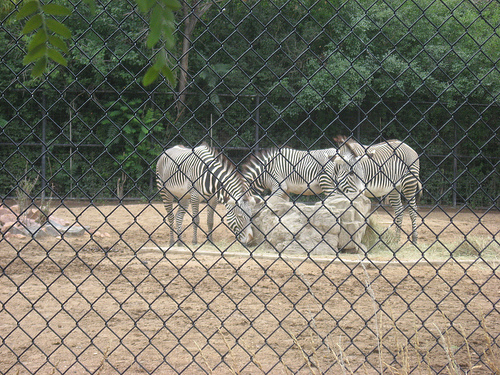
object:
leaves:
[45, 17, 72, 40]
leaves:
[161, 65, 175, 88]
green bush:
[0, 0, 499, 206]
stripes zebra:
[241, 143, 340, 203]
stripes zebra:
[328, 135, 423, 246]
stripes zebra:
[155, 140, 262, 248]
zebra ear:
[356, 150, 375, 163]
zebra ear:
[328, 153, 346, 164]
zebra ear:
[224, 196, 240, 206]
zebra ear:
[250, 195, 263, 208]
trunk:
[452, 123, 457, 207]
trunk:
[357, 103, 361, 141]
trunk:
[379, 117, 382, 142]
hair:
[201, 141, 249, 203]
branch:
[177, 0, 215, 119]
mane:
[333, 135, 359, 165]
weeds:
[9, 157, 55, 227]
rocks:
[0, 204, 90, 239]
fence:
[0, 1, 499, 374]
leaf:
[15, 5, 40, 20]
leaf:
[40, 3, 73, 16]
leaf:
[142, 67, 160, 86]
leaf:
[162, 20, 176, 49]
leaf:
[46, 48, 68, 66]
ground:
[1, 203, 500, 374]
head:
[222, 196, 261, 245]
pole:
[40, 91, 46, 197]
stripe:
[285, 147, 286, 174]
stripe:
[290, 149, 295, 181]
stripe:
[296, 150, 299, 184]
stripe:
[305, 146, 312, 183]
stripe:
[310, 162, 318, 181]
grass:
[361, 209, 500, 258]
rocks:
[252, 193, 372, 258]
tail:
[417, 178, 422, 200]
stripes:
[394, 157, 398, 175]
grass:
[180, 237, 288, 260]